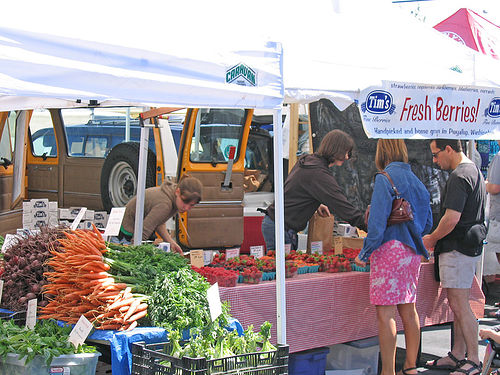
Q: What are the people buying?
A: Produce.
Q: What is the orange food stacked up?
A: Carrots.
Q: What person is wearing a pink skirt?
A: The female shopper.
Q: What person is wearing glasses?
A: The male shopper.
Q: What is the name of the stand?
A: Tim's Fresh Berries.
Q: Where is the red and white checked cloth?
A: On the table.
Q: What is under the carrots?
A: A blue cloth.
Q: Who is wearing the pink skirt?
A: The woman with the blue jacket.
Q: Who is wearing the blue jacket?
A: The woman with the pink skirt.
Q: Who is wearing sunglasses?
A: The man.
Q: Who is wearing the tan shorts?
A: The man in the black shirt.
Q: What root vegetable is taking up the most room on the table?
A: The carrots.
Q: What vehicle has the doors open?
A: The yellow van.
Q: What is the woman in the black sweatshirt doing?
A: Helping customers.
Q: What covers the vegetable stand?
A: A tent.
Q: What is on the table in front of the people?
A: Containers of strawberries.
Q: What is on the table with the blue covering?
A: A stack of vegetables.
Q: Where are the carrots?
A: On the table with the blue cover.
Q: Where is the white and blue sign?
A: Over the fruit stand.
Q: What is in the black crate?
A: Green vegetables.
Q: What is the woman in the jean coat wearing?
A: A pink and white skirt.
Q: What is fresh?
A: Berries.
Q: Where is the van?
A: Behind the girl.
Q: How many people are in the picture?
A: 4.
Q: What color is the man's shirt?
A: Black.